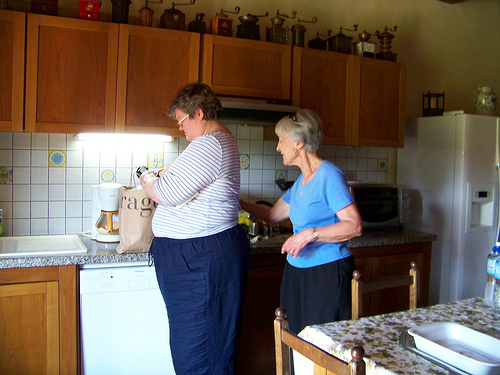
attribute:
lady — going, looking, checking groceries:
[243, 114, 364, 330]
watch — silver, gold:
[311, 226, 320, 244]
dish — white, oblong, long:
[408, 318, 499, 375]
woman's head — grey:
[270, 105, 327, 151]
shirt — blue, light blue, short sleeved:
[279, 162, 364, 266]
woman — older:
[149, 85, 263, 375]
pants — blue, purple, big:
[150, 226, 249, 375]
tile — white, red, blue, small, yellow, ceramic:
[4, 150, 118, 188]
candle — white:
[97, 184, 120, 210]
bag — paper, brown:
[117, 178, 161, 258]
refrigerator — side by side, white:
[399, 111, 500, 299]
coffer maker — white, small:
[91, 183, 121, 213]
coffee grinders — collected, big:
[36, 0, 400, 56]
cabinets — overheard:
[7, 12, 406, 150]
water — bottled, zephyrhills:
[484, 240, 499, 311]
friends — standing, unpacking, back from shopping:
[151, 82, 365, 375]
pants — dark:
[284, 257, 357, 330]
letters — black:
[114, 197, 159, 216]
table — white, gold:
[310, 297, 499, 375]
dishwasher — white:
[84, 267, 181, 375]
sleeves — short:
[327, 171, 355, 215]